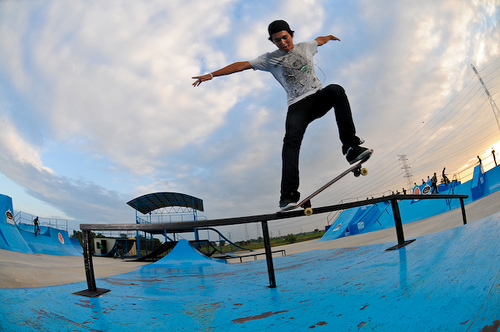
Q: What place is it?
A: It is a skate park.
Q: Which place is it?
A: It is a skate park.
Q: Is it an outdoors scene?
A: Yes, it is outdoors.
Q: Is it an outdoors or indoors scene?
A: It is outdoors.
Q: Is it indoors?
A: No, it is outdoors.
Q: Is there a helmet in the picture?
A: No, there are no helmets.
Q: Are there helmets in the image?
A: No, there are no helmets.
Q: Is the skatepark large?
A: Yes, the skatepark is large.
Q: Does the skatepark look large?
A: Yes, the skatepark is large.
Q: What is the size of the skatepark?
A: The skatepark is large.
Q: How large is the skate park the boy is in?
A: The skate park is large.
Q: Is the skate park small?
A: No, the skate park is large.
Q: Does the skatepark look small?
A: No, the skatepark is large.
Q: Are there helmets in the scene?
A: No, there are no helmets.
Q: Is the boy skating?
A: Yes, the boy is skating.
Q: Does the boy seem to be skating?
A: Yes, the boy is skating.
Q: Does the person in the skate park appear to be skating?
A: Yes, the boy is skating.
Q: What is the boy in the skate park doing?
A: The boy is skating.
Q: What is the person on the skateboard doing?
A: The boy is skating.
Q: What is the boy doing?
A: The boy is skating.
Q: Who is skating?
A: The boy is skating.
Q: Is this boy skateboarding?
A: No, the boy is skating.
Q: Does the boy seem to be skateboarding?
A: No, the boy is skating.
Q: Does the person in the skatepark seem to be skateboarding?
A: No, the boy is skating.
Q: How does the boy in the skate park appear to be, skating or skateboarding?
A: The boy is skating.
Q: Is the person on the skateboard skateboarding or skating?
A: The boy is skating.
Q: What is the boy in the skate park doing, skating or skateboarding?
A: The boy is skating.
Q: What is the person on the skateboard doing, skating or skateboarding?
A: The boy is skating.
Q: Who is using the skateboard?
A: The boy is using the skateboard.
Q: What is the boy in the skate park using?
A: The boy is using a skateboard.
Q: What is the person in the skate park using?
A: The boy is using a skateboard.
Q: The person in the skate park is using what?
A: The boy is using a skateboard.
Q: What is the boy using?
A: The boy is using a skateboard.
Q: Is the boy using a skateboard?
A: Yes, the boy is using a skateboard.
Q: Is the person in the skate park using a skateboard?
A: Yes, the boy is using a skateboard.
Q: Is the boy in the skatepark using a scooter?
A: No, the boy is using a skateboard.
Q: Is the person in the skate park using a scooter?
A: No, the boy is using a skateboard.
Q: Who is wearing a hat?
A: The boy is wearing a hat.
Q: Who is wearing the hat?
A: The boy is wearing a hat.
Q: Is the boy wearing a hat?
A: Yes, the boy is wearing a hat.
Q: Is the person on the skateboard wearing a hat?
A: Yes, the boy is wearing a hat.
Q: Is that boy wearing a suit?
A: No, the boy is wearing a hat.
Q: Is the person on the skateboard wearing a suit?
A: No, the boy is wearing a hat.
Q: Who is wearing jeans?
A: The boy is wearing jeans.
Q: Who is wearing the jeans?
A: The boy is wearing jeans.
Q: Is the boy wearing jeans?
A: Yes, the boy is wearing jeans.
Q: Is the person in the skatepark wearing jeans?
A: Yes, the boy is wearing jeans.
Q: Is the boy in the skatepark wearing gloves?
A: No, the boy is wearing jeans.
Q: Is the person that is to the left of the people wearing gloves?
A: No, the boy is wearing jeans.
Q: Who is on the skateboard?
A: The boy is on the skateboard.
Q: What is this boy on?
A: The boy is on the skateboard.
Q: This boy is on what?
A: The boy is on the skateboard.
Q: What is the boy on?
A: The boy is on the skateboard.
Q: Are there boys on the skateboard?
A: Yes, there is a boy on the skateboard.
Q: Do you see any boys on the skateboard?
A: Yes, there is a boy on the skateboard.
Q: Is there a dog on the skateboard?
A: No, there is a boy on the skateboard.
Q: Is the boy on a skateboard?
A: Yes, the boy is on a skateboard.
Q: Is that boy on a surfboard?
A: No, the boy is on a skateboard.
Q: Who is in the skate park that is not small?
A: The boy is in the skatepark.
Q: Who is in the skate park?
A: The boy is in the skatepark.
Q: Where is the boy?
A: The boy is in the skate park.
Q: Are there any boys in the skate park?
A: Yes, there is a boy in the skate park.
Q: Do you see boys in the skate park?
A: Yes, there is a boy in the skate park.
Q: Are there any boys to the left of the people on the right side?
A: Yes, there is a boy to the left of the people.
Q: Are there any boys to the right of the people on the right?
A: No, the boy is to the left of the people.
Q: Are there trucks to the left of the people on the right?
A: No, there is a boy to the left of the people.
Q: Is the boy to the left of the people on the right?
A: Yes, the boy is to the left of the people.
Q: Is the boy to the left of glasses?
A: No, the boy is to the left of the people.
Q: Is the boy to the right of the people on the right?
A: No, the boy is to the left of the people.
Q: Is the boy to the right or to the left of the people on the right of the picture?
A: The boy is to the left of the people.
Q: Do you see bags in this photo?
A: No, there are no bags.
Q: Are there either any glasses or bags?
A: No, there are no bags or glasses.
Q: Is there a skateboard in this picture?
A: Yes, there is a skateboard.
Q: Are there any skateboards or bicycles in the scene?
A: Yes, there is a skateboard.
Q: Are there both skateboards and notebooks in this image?
A: No, there is a skateboard but no notebooks.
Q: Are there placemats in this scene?
A: No, there are no placemats.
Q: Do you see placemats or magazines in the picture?
A: No, there are no placemats or magazines.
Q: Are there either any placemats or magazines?
A: No, there are no placemats or magazines.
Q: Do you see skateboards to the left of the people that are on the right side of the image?
A: Yes, there is a skateboard to the left of the people.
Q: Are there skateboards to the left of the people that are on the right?
A: Yes, there is a skateboard to the left of the people.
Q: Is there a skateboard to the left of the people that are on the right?
A: Yes, there is a skateboard to the left of the people.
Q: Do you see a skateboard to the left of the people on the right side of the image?
A: Yes, there is a skateboard to the left of the people.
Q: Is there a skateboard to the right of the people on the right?
A: No, the skateboard is to the left of the people.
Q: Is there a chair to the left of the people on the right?
A: No, there is a skateboard to the left of the people.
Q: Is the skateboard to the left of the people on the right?
A: Yes, the skateboard is to the left of the people.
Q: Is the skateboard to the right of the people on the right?
A: No, the skateboard is to the left of the people.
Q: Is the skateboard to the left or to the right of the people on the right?
A: The skateboard is to the left of the people.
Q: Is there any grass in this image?
A: Yes, there is grass.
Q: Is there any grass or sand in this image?
A: Yes, there is grass.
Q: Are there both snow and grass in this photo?
A: No, there is grass but no snow.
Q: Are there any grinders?
A: No, there are no grinders.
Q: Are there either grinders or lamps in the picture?
A: No, there are no grinders or lamps.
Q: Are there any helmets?
A: No, there are no helmets.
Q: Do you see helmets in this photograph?
A: No, there are no helmets.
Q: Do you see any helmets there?
A: No, there are no helmets.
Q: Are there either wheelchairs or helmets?
A: No, there are no helmets or wheelchairs.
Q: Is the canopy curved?
A: Yes, the canopy is curved.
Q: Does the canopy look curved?
A: Yes, the canopy is curved.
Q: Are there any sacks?
A: No, there are no sacks.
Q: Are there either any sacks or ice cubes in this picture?
A: No, there are no sacks or ice cubes.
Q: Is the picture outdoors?
A: Yes, the picture is outdoors.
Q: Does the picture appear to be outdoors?
A: Yes, the picture is outdoors.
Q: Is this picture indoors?
A: No, the picture is outdoors.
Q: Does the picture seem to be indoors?
A: No, the picture is outdoors.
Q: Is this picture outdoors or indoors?
A: The picture is outdoors.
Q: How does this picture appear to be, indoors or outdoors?
A: The picture is outdoors.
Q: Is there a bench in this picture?
A: Yes, there is a bench.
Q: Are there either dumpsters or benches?
A: Yes, there is a bench.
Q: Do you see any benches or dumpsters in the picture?
A: Yes, there is a bench.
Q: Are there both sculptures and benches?
A: No, there is a bench but no sculptures.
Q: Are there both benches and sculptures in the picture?
A: No, there is a bench but no sculptures.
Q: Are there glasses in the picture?
A: No, there are no glasses.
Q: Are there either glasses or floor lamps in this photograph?
A: No, there are no glasses or floor lamps.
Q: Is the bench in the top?
A: No, the bench is in the bottom of the image.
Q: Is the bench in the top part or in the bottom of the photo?
A: The bench is in the bottom of the image.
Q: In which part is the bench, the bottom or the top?
A: The bench is in the bottom of the image.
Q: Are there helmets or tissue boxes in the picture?
A: No, there are no helmets or tissue boxes.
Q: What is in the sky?
A: The clouds are in the sky.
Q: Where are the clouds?
A: The clouds are in the sky.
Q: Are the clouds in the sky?
A: Yes, the clouds are in the sky.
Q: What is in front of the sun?
A: The clouds are in front of the sun.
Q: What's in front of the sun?
A: The clouds are in front of the sun.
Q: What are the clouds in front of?
A: The clouds are in front of the sun.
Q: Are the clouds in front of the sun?
A: Yes, the clouds are in front of the sun.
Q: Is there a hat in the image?
A: Yes, there is a hat.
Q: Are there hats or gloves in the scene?
A: Yes, there is a hat.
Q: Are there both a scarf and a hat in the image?
A: No, there is a hat but no scarves.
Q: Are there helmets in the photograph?
A: No, there are no helmets.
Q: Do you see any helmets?
A: No, there are no helmets.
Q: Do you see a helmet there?
A: No, there are no helmets.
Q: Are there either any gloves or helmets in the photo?
A: No, there are no helmets or gloves.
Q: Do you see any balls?
A: No, there are no balls.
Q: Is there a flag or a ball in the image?
A: No, there are no balls or flags.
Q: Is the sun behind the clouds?
A: Yes, the sun is behind the clouds.